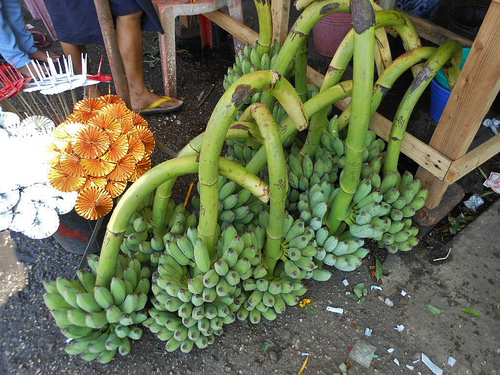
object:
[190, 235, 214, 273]
banana